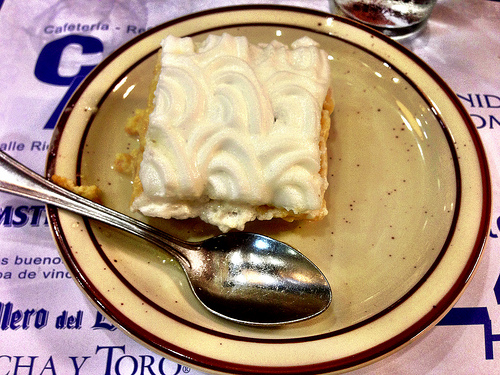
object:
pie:
[113, 32, 338, 233]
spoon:
[0, 148, 334, 327]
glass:
[330, 0, 435, 38]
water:
[354, 3, 424, 21]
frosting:
[127, 34, 331, 233]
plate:
[43, 4, 492, 374]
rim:
[476, 112, 494, 283]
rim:
[179, 361, 376, 373]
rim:
[57, 220, 85, 296]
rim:
[174, 2, 344, 15]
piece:
[51, 173, 108, 205]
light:
[227, 241, 289, 293]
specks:
[376, 102, 419, 162]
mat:
[0, 0, 499, 374]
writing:
[0, 299, 85, 330]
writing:
[0, 204, 46, 227]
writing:
[0, 344, 191, 374]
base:
[360, 22, 427, 42]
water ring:
[26, 0, 151, 70]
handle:
[0, 149, 180, 256]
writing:
[42, 21, 110, 35]